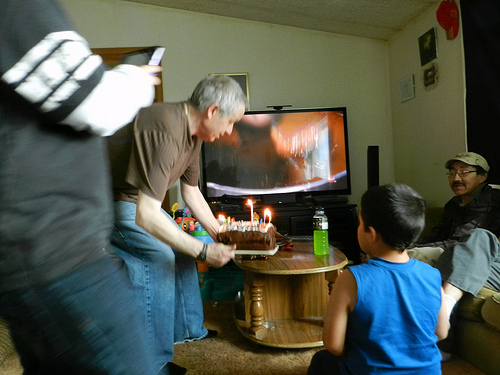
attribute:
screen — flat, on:
[200, 106, 352, 198]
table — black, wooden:
[192, 203, 363, 263]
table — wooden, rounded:
[230, 240, 352, 351]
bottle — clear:
[310, 205, 332, 257]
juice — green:
[312, 231, 331, 255]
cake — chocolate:
[214, 221, 276, 250]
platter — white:
[232, 245, 280, 255]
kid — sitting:
[307, 181, 449, 374]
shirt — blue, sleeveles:
[341, 260, 442, 374]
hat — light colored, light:
[444, 151, 492, 173]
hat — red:
[434, 0, 461, 42]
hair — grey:
[189, 73, 248, 116]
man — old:
[105, 73, 248, 373]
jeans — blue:
[109, 199, 208, 367]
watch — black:
[195, 242, 211, 263]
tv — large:
[196, 104, 355, 207]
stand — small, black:
[249, 194, 309, 208]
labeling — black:
[310, 218, 330, 231]